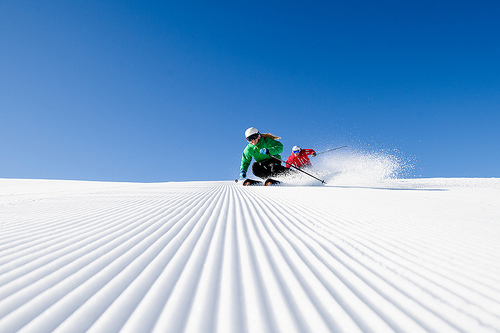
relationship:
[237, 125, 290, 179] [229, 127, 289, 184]
people wears jacket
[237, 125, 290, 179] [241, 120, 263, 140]
people wears helmet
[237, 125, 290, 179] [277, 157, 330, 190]
people holds ski poles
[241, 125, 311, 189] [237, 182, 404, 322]
people down mountain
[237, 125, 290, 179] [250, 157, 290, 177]
people wears pants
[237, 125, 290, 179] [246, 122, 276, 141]
people has hair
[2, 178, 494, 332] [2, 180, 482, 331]
groves formed in snow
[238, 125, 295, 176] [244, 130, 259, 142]
person wearing glasses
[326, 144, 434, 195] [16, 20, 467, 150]
dust raising to sky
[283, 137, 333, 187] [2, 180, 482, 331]
man on snow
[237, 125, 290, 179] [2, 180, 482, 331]
people in snow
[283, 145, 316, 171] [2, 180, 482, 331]
person in snow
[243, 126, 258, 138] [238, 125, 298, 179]
helmet on woman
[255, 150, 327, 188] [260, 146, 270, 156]
skipole in hand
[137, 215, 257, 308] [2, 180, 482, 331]
lines in snow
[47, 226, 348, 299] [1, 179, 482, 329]
snow on ground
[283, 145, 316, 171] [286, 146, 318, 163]
person in jacket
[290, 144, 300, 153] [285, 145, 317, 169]
helmet on man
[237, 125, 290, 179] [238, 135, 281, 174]
people wearing a green coat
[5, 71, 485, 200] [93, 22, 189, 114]
part of a sky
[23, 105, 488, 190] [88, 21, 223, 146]
part of a sky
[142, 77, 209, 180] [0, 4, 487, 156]
part of a sky